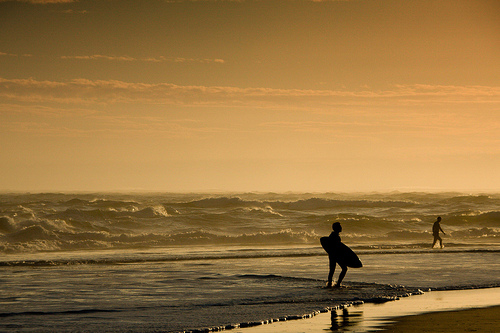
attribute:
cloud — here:
[4, 4, 488, 183]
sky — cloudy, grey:
[1, 4, 499, 186]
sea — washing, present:
[2, 190, 499, 294]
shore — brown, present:
[0, 256, 500, 332]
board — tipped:
[320, 234, 367, 270]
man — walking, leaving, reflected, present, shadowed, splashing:
[320, 215, 369, 286]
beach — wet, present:
[3, 245, 495, 329]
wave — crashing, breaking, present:
[3, 189, 483, 247]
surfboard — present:
[320, 234, 366, 267]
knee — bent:
[340, 265, 352, 276]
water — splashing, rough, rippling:
[3, 232, 498, 253]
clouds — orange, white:
[1, 24, 496, 179]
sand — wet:
[4, 249, 498, 331]